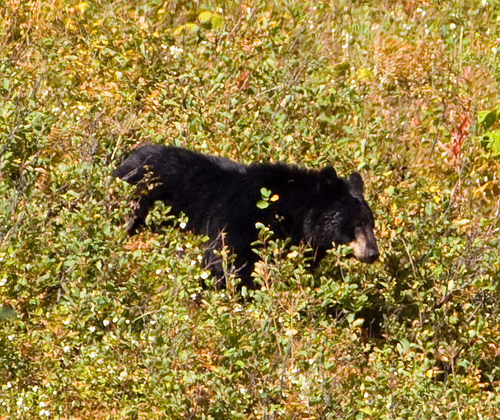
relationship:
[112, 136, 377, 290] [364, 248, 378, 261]
bear has nose